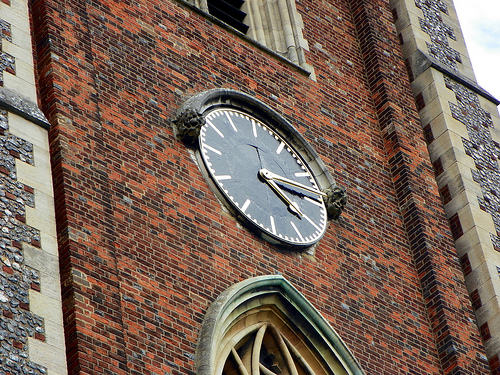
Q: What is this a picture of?
A: A clock.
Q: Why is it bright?
A: It's daylight.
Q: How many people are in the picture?
A: None.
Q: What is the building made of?
A: Bricks.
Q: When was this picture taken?
A: During the day.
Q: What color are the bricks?
A: Red.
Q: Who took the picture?
A: The photographer.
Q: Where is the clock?
A: On a building.